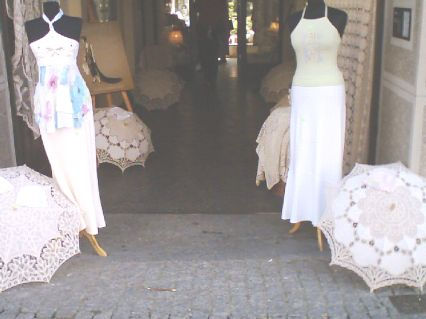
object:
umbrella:
[0, 163, 82, 292]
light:
[169, 27, 185, 49]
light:
[267, 19, 283, 32]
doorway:
[162, 1, 265, 69]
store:
[0, 0, 426, 319]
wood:
[79, 229, 106, 257]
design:
[44, 70, 59, 93]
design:
[68, 83, 88, 116]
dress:
[31, 13, 109, 236]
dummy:
[24, 2, 108, 255]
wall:
[346, 0, 370, 154]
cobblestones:
[0, 259, 426, 319]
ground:
[0, 99, 426, 319]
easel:
[72, 19, 135, 122]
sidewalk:
[0, 59, 426, 319]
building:
[0, 0, 426, 319]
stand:
[88, 89, 138, 114]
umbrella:
[92, 104, 157, 172]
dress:
[278, 4, 346, 227]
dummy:
[279, 0, 347, 236]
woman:
[80, 34, 122, 84]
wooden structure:
[87, 89, 135, 114]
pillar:
[233, 0, 247, 92]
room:
[2, 0, 426, 319]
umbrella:
[319, 161, 426, 293]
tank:
[30, 10, 92, 130]